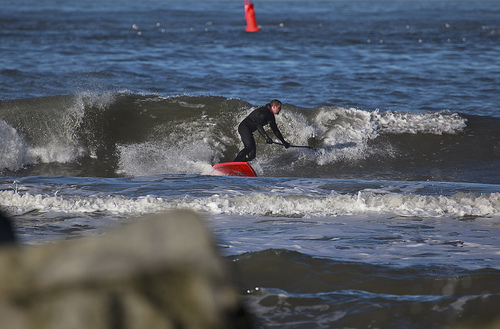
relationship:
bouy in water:
[242, 2, 263, 32] [0, 2, 494, 110]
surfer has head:
[229, 97, 290, 163] [264, 94, 283, 114]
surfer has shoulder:
[229, 97, 290, 163] [261, 103, 268, 111]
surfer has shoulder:
[229, 97, 290, 163] [259, 106, 270, 113]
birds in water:
[128, 19, 148, 39] [0, 2, 494, 110]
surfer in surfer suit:
[233, 97, 290, 162] [225, 104, 281, 164]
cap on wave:
[328, 93, 403, 155] [395, 133, 455, 213]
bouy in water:
[226, 12, 284, 32] [220, 41, 329, 81]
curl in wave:
[59, 93, 159, 156] [47, 149, 137, 203]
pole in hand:
[286, 137, 321, 157] [260, 130, 289, 150]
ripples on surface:
[279, 73, 372, 105] [364, 63, 406, 84]